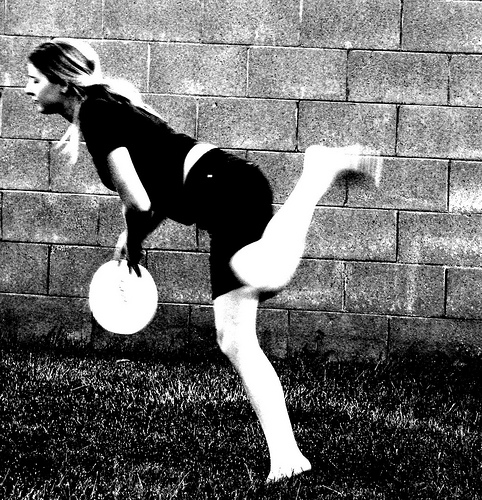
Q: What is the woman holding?
A: Frisbee.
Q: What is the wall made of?
A: Cinder blocks.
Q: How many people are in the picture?
A: 1.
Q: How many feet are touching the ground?
A: 1.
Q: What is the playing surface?
A: Grass.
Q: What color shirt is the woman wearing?
A: Black.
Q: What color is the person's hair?
A: Blonde.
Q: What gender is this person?
A: Female.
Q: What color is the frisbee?
A: White.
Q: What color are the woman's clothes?
A: Black.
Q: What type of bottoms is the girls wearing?
A: Shorts.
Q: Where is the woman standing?
A: Grass.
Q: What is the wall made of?
A: Brick.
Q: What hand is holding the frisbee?
A: Right.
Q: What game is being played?
A: Frisbee.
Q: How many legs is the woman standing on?
A: One.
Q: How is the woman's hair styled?
A: Ponytail.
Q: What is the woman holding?
A: Frisbee.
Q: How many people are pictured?
A: One.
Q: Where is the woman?
A: On the grass.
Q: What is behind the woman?
A: Brick wall.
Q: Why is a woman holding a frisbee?
A: To play with it.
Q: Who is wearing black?
A: The woman.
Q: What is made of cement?
A: The wall.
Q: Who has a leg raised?
A: A woman.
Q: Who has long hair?
A: The lady.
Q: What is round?
A: The frisbee.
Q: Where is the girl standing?
A: On grass.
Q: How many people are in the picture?
A: 1.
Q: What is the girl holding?
A: A Frisbee.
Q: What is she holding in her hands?
A: A Frisbee.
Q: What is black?
A: The woman's clothes.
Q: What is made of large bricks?
A: The wall in back of the woman.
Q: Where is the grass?
A: Under the woman's feet.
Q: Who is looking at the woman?
A: The photographer.